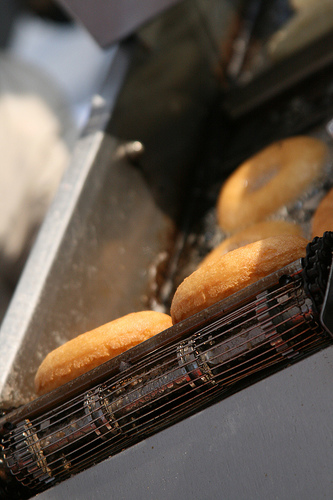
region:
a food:
[47, 296, 194, 401]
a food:
[58, 240, 325, 412]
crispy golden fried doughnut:
[170, 220, 306, 323]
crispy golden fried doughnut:
[29, 292, 174, 404]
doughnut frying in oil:
[207, 131, 328, 231]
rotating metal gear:
[292, 225, 331, 349]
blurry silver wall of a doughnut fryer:
[4, 26, 183, 356]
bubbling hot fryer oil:
[264, 191, 319, 233]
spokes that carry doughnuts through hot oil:
[3, 284, 330, 491]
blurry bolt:
[111, 131, 145, 165]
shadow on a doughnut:
[254, 211, 312, 270]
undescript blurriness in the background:
[0, 0, 108, 288]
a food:
[31, 241, 234, 381]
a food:
[14, 249, 256, 467]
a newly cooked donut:
[33, 300, 166, 404]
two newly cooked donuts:
[38, 269, 331, 401]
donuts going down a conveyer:
[2, 291, 332, 469]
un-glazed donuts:
[20, 273, 275, 431]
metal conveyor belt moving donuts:
[14, 293, 314, 498]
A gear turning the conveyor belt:
[5, 416, 67, 495]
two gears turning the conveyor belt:
[75, 335, 229, 449]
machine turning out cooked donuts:
[11, 268, 330, 498]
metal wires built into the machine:
[96, 285, 314, 432]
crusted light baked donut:
[39, 313, 157, 395]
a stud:
[83, 121, 159, 185]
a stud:
[98, 125, 151, 155]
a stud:
[96, 89, 162, 198]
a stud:
[101, 96, 143, 164]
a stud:
[88, 121, 200, 182]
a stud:
[104, 131, 237, 210]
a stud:
[89, 74, 169, 191]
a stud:
[96, 139, 180, 195]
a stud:
[93, 116, 196, 204]